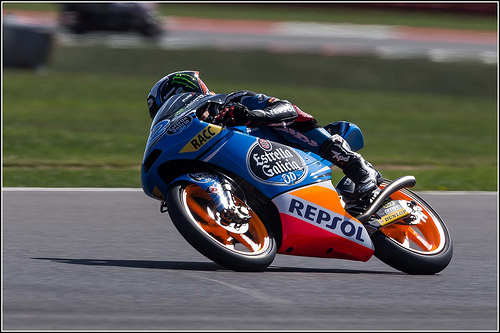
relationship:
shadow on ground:
[35, 245, 222, 277] [2, 180, 498, 328]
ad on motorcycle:
[251, 188, 391, 265] [134, 106, 452, 275]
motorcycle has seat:
[134, 95, 459, 269] [325, 121, 357, 138]